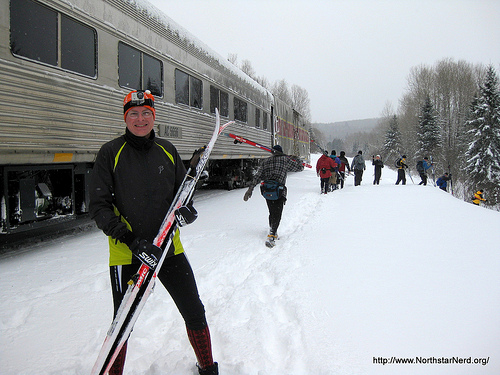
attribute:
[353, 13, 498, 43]
cloud — white 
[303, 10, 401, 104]
sky — blue 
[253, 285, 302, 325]
snow — white 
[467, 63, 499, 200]
pine tree — snow covered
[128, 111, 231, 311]
skis — white 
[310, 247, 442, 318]
snow — tall 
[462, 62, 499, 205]
tree — snow covered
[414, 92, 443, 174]
tree — snow covered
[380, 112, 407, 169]
tree — snow covered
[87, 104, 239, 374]
skis — pair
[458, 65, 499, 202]
tree — snow covered, evergreen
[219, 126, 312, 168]
skis — red 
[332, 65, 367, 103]
clouds — white 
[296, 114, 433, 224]
people — group, walking in line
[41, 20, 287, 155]
train — silver , long 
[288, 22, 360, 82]
clouds — white 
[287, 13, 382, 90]
sky — blue 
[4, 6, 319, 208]
train — silver 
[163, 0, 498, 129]
sky — blue 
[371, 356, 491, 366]
address — black 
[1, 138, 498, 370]
hill — snow covered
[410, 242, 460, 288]
snow — white 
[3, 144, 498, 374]
snow — white 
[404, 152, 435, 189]
person — blue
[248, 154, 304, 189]
shirt — black, white, plaid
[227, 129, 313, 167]
skiis — red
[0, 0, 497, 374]
snow — white 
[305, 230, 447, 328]
snow — white 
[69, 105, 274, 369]
attire — skiing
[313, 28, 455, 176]
clouds — white 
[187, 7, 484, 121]
sky — blue 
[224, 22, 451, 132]
sky — blue 